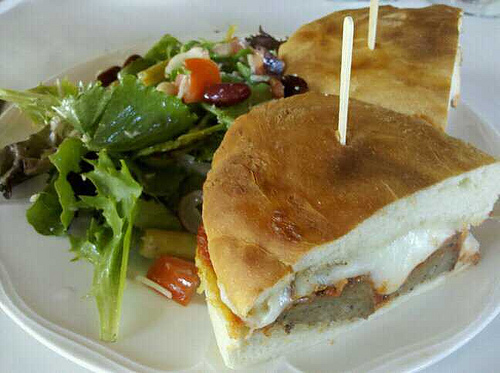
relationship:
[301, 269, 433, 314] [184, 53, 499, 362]
meat on sandwich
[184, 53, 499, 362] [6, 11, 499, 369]
sandwich on plate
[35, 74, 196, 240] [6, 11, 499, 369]
salad on plate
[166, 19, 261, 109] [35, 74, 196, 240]
crouton on salad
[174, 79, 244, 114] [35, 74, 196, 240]
bean in salad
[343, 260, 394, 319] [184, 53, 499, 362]
sauce on sandwich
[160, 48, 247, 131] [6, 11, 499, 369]
pepperoni on plate